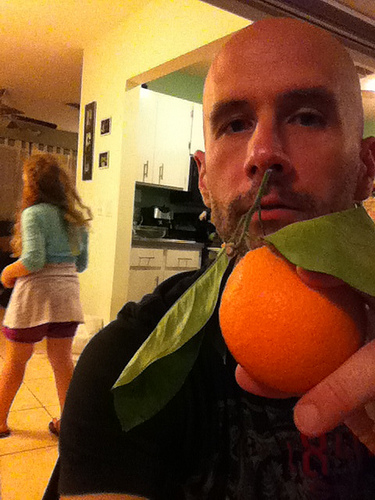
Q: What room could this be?
A: It is a kitchen.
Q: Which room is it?
A: It is a kitchen.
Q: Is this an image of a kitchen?
A: Yes, it is showing a kitchen.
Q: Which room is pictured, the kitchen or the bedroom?
A: It is the kitchen.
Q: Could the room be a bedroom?
A: No, it is a kitchen.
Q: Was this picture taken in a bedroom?
A: No, the picture was taken in a kitchen.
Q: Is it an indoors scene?
A: Yes, it is indoors.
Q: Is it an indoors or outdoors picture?
A: It is indoors.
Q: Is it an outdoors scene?
A: No, it is indoors.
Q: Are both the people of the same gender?
A: No, they are both male and female.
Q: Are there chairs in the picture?
A: No, there are no chairs.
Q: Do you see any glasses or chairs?
A: No, there are no chairs or glasses.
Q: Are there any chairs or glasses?
A: No, there are no chairs or glasses.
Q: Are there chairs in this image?
A: No, there are no chairs.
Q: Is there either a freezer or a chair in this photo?
A: No, there are no chairs or refrigerators.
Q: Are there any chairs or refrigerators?
A: No, there are no chairs or refrigerators.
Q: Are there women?
A: Yes, there is a woman.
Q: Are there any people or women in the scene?
A: Yes, there is a woman.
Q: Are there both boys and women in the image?
A: No, there is a woman but no boys.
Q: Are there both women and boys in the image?
A: No, there is a woman but no boys.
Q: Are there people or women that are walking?
A: Yes, the woman is walking.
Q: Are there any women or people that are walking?
A: Yes, the woman is walking.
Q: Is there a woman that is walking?
A: Yes, there is a woman that is walking.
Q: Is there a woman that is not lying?
A: Yes, there is a woman that is walking.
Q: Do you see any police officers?
A: No, there are no police officers.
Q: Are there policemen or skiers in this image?
A: No, there are no policemen or skiers.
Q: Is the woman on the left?
A: Yes, the woman is on the left of the image.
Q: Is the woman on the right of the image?
A: No, the woman is on the left of the image.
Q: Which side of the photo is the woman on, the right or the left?
A: The woman is on the left of the image.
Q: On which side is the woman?
A: The woman is on the left of the image.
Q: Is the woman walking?
A: Yes, the woman is walking.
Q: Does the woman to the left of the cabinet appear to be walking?
A: Yes, the woman is walking.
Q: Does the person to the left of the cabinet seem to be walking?
A: Yes, the woman is walking.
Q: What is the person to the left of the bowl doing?
A: The woman is walking.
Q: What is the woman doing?
A: The woman is walking.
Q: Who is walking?
A: The woman is walking.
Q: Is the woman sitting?
A: No, the woman is walking.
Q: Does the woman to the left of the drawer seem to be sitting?
A: No, the woman is walking.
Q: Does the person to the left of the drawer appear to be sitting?
A: No, the woman is walking.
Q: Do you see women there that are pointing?
A: No, there is a woman but she is walking.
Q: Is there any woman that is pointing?
A: No, there is a woman but she is walking.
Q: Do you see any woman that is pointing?
A: No, there is a woman but she is walking.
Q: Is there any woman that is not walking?
A: No, there is a woman but she is walking.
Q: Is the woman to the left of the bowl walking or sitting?
A: The woman is walking.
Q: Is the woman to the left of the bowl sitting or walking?
A: The woman is walking.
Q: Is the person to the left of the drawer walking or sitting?
A: The woman is walking.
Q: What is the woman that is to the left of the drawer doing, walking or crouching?
A: The woman is walking.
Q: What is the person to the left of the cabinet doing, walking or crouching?
A: The woman is walking.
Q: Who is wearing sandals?
A: The woman is wearing sandals.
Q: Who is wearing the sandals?
A: The woman is wearing sandals.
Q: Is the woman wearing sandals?
A: Yes, the woman is wearing sandals.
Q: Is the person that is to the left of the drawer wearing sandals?
A: Yes, the woman is wearing sandals.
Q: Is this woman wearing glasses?
A: No, the woman is wearing sandals.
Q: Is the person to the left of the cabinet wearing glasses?
A: No, the woman is wearing sandals.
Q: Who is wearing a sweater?
A: The woman is wearing a sweater.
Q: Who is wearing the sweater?
A: The woman is wearing a sweater.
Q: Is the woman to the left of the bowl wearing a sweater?
A: Yes, the woman is wearing a sweater.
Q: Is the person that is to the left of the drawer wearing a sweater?
A: Yes, the woman is wearing a sweater.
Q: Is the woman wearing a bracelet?
A: No, the woman is wearing a sweater.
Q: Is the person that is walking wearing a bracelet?
A: No, the woman is wearing a sweater.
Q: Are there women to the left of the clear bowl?
A: Yes, there is a woman to the left of the bowl.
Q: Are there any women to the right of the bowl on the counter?
A: No, the woman is to the left of the bowl.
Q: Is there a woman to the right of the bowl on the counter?
A: No, the woman is to the left of the bowl.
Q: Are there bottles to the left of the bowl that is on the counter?
A: No, there is a woman to the left of the bowl.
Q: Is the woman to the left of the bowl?
A: Yes, the woman is to the left of the bowl.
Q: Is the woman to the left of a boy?
A: No, the woman is to the left of the bowl.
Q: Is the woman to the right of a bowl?
A: No, the woman is to the left of a bowl.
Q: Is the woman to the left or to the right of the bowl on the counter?
A: The woman is to the left of the bowl.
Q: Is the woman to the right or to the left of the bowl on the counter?
A: The woman is to the left of the bowl.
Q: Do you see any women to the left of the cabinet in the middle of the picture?
A: Yes, there is a woman to the left of the cabinet.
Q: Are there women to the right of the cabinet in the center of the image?
A: No, the woman is to the left of the cabinet.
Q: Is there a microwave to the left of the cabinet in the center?
A: No, there is a woman to the left of the cabinet.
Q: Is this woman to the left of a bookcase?
A: No, the woman is to the left of the cabinet.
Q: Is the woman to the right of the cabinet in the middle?
A: No, the woman is to the left of the cabinet.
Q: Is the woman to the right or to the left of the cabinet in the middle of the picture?
A: The woman is to the left of the cabinet.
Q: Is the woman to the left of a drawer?
A: Yes, the woman is to the left of a drawer.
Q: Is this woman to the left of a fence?
A: No, the woman is to the left of a drawer.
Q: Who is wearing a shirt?
A: The woman is wearing a shirt.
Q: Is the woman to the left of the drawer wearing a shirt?
A: Yes, the woman is wearing a shirt.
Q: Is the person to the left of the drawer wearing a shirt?
A: Yes, the woman is wearing a shirt.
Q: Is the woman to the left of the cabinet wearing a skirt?
A: No, the woman is wearing a shirt.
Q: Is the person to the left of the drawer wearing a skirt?
A: No, the woman is wearing a shirt.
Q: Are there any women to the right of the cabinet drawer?
A: No, the woman is to the left of the drawer.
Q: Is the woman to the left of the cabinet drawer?
A: Yes, the woman is to the left of the drawer.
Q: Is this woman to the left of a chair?
A: No, the woman is to the left of the drawer.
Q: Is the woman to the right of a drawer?
A: No, the woman is to the left of a drawer.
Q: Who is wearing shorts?
A: The woman is wearing shorts.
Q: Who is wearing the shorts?
A: The woman is wearing shorts.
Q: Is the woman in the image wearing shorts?
A: Yes, the woman is wearing shorts.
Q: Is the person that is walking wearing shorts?
A: Yes, the woman is wearing shorts.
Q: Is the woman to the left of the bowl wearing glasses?
A: No, the woman is wearing shorts.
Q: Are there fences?
A: No, there are no fences.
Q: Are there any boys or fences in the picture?
A: No, there are no fences or boys.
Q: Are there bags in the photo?
A: No, there are no bags.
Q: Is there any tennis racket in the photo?
A: No, there are no rackets.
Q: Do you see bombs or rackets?
A: No, there are no rackets or bombs.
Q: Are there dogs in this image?
A: No, there are no dogs.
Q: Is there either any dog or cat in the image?
A: No, there are no dogs or cats.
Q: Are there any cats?
A: No, there are no cats.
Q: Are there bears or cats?
A: No, there are no cats or bears.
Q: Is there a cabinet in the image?
A: Yes, there is a cabinet.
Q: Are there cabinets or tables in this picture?
A: Yes, there is a cabinet.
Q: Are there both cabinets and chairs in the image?
A: No, there is a cabinet but no chairs.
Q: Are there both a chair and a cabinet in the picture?
A: No, there is a cabinet but no chairs.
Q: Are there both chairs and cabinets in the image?
A: No, there is a cabinet but no chairs.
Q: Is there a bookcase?
A: No, there are no bookcases.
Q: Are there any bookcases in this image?
A: No, there are no bookcases.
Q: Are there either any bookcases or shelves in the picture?
A: No, there are no bookcases or shelves.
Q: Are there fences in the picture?
A: No, there are no fences.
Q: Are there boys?
A: No, there are no boys.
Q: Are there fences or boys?
A: No, there are no boys or fences.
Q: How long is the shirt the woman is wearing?
A: The shirt is long.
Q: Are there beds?
A: No, there are no beds.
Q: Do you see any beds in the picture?
A: No, there are no beds.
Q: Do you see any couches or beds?
A: No, there are no beds or couches.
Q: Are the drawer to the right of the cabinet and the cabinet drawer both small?
A: Yes, both the drawer and the drawer are small.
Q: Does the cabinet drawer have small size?
A: Yes, the drawer is small.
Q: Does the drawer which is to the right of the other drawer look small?
A: Yes, the drawer is small.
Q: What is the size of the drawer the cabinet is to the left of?
A: The drawer is small.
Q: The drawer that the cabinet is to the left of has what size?
A: The drawer is small.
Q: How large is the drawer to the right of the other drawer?
A: The drawer is small.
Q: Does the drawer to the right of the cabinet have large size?
A: No, the drawer is small.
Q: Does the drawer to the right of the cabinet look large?
A: No, the drawer is small.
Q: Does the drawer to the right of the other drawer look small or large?
A: The drawer is small.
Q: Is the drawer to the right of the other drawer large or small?
A: The drawer is small.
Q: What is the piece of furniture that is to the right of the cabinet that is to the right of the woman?
A: The piece of furniture is a drawer.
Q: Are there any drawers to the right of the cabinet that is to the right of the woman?
A: Yes, there is a drawer to the right of the cabinet.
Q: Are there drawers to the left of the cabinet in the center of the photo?
A: No, the drawer is to the right of the cabinet.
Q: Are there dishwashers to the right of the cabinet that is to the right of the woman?
A: No, there is a drawer to the right of the cabinet.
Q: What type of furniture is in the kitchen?
A: The piece of furniture is a drawer.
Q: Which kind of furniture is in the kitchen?
A: The piece of furniture is a drawer.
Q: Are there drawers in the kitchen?
A: Yes, there is a drawer in the kitchen.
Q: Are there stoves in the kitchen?
A: No, there is a drawer in the kitchen.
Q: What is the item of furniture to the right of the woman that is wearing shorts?
A: The piece of furniture is a drawer.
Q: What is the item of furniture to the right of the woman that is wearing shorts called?
A: The piece of furniture is a drawer.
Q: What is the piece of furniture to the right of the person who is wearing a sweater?
A: The piece of furniture is a drawer.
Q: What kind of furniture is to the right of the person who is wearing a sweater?
A: The piece of furniture is a drawer.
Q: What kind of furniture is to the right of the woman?
A: The piece of furniture is a drawer.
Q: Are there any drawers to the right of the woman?
A: Yes, there is a drawer to the right of the woman.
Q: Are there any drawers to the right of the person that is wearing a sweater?
A: Yes, there is a drawer to the right of the woman.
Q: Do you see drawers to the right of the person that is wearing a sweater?
A: Yes, there is a drawer to the right of the woman.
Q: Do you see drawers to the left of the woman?
A: No, the drawer is to the right of the woman.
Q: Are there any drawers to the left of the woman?
A: No, the drawer is to the right of the woman.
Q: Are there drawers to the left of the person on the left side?
A: No, the drawer is to the right of the woman.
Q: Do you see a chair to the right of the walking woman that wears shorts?
A: No, there is a drawer to the right of the woman.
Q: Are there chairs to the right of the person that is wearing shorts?
A: No, there is a drawer to the right of the woman.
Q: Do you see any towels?
A: No, there are no towels.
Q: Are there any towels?
A: No, there are no towels.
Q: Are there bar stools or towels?
A: No, there are no towels or bar stools.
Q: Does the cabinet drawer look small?
A: Yes, the drawer is small.